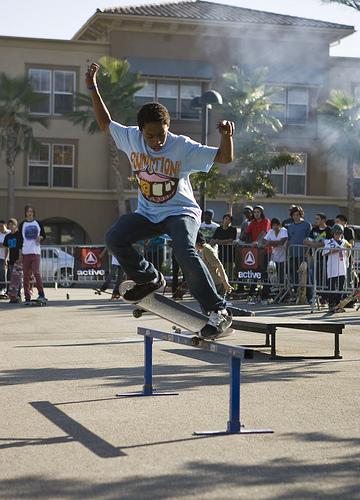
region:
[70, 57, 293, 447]
young man skateboarding on a ramp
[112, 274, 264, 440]
black skateboard tilted on the blue ramp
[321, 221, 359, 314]
young boy standing behind the fence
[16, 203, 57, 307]
young man standing with one foot on his skateboard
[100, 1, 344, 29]
dark brown roof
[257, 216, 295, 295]
man leaning over the fence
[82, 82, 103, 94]
thin blue wristband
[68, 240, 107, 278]
small banner hanging on the fence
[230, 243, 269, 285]
red, black, and white banner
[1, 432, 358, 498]
shadows on the ground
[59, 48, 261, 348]
young man skateboarding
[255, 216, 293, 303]
man leaning against the fence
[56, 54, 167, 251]
tall green palm tree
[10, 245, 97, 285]
car on the road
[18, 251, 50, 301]
copper pants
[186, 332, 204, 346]
wheel on the skateboard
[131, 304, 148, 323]
another wheel on skateboard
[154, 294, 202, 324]
part of the skateboard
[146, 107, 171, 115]
hair on boy's head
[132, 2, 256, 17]
roof on the building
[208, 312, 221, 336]
athletic shoe on foot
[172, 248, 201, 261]
knee on the boy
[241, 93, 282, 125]
leaves in the tree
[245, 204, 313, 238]
people looking at skateboarder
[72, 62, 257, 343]
boy on the skateboard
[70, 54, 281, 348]
boy on skateboard in air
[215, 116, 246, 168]
left arm of boy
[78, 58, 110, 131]
right arm of boy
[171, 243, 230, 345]
left leg of boy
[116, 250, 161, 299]
right leg of boy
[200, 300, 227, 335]
left shoe of boy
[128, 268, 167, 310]
right shoe of boy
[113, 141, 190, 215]
blue tshirt on blue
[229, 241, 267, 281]
active advertisement on fence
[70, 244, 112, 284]
active advertisement on fence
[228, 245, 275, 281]
sign on wall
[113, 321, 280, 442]
blue pole to do skateboard tricks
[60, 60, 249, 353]
boy on a skateboard doing it on a rail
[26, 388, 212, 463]
a shadow of a rail on the cement court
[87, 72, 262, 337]
the boy in the blue shirt has his arms in the air for balance on his skateboard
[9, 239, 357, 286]
a metal white gate surrounds the court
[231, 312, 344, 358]
a metal table in skate park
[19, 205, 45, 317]
a guy in a white shirt with his skateboard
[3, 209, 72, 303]
white car parked out on street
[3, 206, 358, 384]
people outside the gate watching the skateboarder